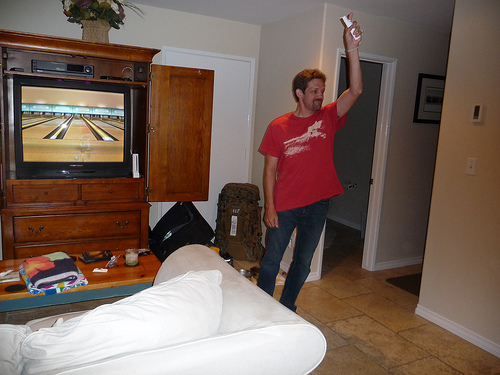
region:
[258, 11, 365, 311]
Man holding game controller in air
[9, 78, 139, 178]
Television in cabinet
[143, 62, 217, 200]
Open wooden cabinet door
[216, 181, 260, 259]
Suitcase in the corner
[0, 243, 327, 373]
White sofa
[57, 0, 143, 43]
Plant on top of cabinet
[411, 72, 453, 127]
Picture on the wall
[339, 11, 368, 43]
Game controller in man's hand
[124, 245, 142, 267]
Candle on the table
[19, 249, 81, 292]
Folded towel on the table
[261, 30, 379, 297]
man in red shirt playing wii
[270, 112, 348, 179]
white design on red shirt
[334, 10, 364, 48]
white wii remote in man's hand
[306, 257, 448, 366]
tile floor in living room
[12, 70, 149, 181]
flat screened tv in living room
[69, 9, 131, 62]
flowers above tv in pot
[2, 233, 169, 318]
wooden coffee table near couch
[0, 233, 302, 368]
white couch in foreground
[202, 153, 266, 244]
luggage up against door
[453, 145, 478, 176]
white light switch on wall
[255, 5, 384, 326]
man stangin in red shirt and blue jeans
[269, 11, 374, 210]
man holding up a white game controller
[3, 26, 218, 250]
brown wood entertainment center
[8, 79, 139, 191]
tv displaying a bowling video game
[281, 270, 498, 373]
brown tile floors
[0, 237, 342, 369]
white couch in front of TV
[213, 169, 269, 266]
backpack in corner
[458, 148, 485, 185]
white light switch on wall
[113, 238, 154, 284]
candle on wood table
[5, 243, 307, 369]
wood table in front of couch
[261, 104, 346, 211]
red and white tee shirt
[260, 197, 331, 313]
dark blue denim jeans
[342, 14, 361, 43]
white video game remote control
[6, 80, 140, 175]
television on wooden cabinet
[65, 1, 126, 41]
flowers on top of cabinet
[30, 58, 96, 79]
dvd player on cabinet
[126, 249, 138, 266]
white candle on table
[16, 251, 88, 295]
beach towels on table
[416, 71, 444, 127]
picture hanging on wall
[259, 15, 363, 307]
man playing video game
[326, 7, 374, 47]
He is holding a remote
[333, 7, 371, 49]
The remote is white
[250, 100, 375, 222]
A red and white shirt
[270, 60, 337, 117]
The person is looking at something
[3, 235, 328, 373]
Couch is white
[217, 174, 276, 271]
Item in the corner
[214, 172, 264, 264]
Item is brown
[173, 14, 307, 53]
Walls are white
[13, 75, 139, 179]
The tv is on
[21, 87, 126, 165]
This is Wii Bowling